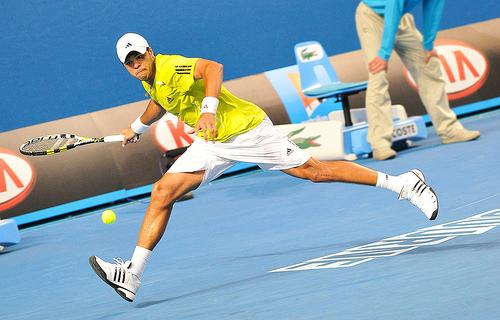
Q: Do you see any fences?
A: No, there are no fences.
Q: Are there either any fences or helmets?
A: No, there are no fences or helmets.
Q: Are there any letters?
A: Yes, there are letters.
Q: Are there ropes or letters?
A: Yes, there are letters.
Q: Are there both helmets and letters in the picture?
A: No, there are letters but no helmets.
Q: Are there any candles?
A: No, there are no candles.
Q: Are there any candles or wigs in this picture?
A: No, there are no candles or wigs.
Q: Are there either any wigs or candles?
A: No, there are no candles or wigs.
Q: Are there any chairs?
A: Yes, there is a chair.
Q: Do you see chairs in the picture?
A: Yes, there is a chair.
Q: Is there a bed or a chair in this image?
A: Yes, there is a chair.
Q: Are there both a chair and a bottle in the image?
A: No, there is a chair but no bottles.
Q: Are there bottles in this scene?
A: No, there are no bottles.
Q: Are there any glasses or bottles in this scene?
A: No, there are no bottles or glasses.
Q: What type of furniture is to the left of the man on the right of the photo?
A: The piece of furniture is a chair.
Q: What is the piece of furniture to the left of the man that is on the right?
A: The piece of furniture is a chair.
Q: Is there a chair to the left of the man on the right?
A: Yes, there is a chair to the left of the man.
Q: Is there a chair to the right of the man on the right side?
A: No, the chair is to the left of the man.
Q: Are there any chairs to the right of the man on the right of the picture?
A: No, the chair is to the left of the man.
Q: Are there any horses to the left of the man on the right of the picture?
A: No, there is a chair to the left of the man.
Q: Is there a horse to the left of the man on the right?
A: No, there is a chair to the left of the man.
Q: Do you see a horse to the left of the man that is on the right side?
A: No, there is a chair to the left of the man.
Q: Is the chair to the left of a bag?
A: No, the chair is to the left of a man.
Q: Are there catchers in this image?
A: No, there are no catchers.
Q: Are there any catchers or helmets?
A: No, there are no catchers or helmets.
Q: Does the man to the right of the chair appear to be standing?
A: Yes, the man is standing.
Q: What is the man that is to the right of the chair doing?
A: The man is standing.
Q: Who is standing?
A: The man is standing.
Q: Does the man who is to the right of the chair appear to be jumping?
A: No, the man is standing.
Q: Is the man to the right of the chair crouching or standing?
A: The man is standing.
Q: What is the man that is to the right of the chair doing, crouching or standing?
A: The man is standing.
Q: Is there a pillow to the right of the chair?
A: No, there is a man to the right of the chair.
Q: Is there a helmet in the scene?
A: No, there are no helmets.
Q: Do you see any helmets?
A: No, there are no helmets.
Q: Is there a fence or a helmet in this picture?
A: No, there are no helmets or fences.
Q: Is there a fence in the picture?
A: No, there are no fences.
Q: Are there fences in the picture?
A: No, there are no fences.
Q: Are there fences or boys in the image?
A: No, there are no fences or boys.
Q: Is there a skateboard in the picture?
A: No, there are no skateboards.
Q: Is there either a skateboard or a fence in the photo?
A: No, there are no skateboards or fences.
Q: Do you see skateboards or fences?
A: No, there are no skateboards or fences.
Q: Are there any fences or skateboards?
A: No, there are no skateboards or fences.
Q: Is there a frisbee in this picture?
A: No, there are no frisbees.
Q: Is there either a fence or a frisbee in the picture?
A: No, there are no frisbees or fences.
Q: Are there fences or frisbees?
A: No, there are no frisbees or fences.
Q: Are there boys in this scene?
A: No, there are no boys.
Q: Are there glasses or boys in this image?
A: No, there are no boys or glasses.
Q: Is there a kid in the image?
A: No, there are no children.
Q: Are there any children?
A: No, there are no children.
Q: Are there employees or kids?
A: No, there are no kids or employees.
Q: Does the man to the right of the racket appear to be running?
A: Yes, the man is running.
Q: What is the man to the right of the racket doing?
A: The man is running.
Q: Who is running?
A: The man is running.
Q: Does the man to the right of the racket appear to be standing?
A: No, the man is running.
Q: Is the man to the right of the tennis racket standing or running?
A: The man is running.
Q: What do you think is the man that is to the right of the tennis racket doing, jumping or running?
A: The man is running.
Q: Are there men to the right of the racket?
A: Yes, there is a man to the right of the racket.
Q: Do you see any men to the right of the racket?
A: Yes, there is a man to the right of the racket.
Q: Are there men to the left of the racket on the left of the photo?
A: No, the man is to the right of the racket.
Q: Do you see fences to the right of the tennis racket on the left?
A: No, there is a man to the right of the racket.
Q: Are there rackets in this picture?
A: Yes, there is a racket.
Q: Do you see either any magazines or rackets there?
A: Yes, there is a racket.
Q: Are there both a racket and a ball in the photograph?
A: Yes, there are both a racket and a ball.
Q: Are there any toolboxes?
A: No, there are no toolboxes.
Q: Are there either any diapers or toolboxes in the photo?
A: No, there are no toolboxes or diapers.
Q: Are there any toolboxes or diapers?
A: No, there are no toolboxes or diapers.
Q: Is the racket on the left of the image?
A: Yes, the racket is on the left of the image.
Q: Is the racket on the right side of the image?
A: No, the racket is on the left of the image.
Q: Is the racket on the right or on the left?
A: The racket is on the left of the image.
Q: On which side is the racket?
A: The racket is on the left of the image.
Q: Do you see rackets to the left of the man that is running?
A: Yes, there is a racket to the left of the man.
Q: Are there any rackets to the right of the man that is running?
A: No, the racket is to the left of the man.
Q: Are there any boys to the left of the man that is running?
A: No, there is a racket to the left of the man.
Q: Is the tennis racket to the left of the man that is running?
A: Yes, the tennis racket is to the left of the man.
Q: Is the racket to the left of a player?
A: No, the racket is to the left of the man.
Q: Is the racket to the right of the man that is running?
A: No, the racket is to the left of the man.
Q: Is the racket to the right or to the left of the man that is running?
A: The racket is to the left of the man.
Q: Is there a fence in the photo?
A: No, there are no fences.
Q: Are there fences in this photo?
A: No, there are no fences.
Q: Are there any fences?
A: No, there are no fences.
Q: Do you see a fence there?
A: No, there are no fences.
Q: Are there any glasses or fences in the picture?
A: No, there are no fences or glasses.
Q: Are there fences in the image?
A: No, there are no fences.